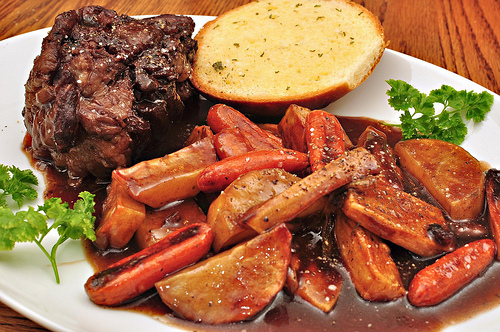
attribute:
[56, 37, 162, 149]
meat — dark, brown, cooked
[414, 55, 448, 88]
plate — white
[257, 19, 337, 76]
bun — orange, gold, brown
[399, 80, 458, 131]
leaves — green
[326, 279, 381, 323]
sauce — brown